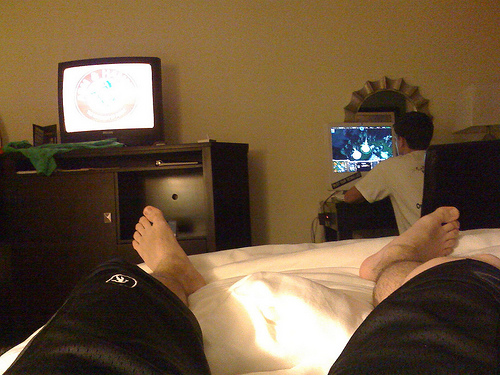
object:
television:
[54, 54, 169, 141]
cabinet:
[5, 145, 253, 336]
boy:
[346, 116, 433, 231]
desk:
[319, 200, 402, 242]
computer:
[326, 123, 397, 193]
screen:
[333, 126, 393, 171]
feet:
[130, 202, 204, 292]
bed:
[4, 227, 499, 374]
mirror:
[356, 90, 413, 113]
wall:
[0, 5, 500, 134]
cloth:
[7, 139, 121, 171]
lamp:
[448, 82, 499, 144]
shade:
[453, 83, 496, 136]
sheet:
[192, 241, 371, 374]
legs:
[6, 275, 214, 373]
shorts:
[7, 258, 500, 375]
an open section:
[118, 171, 213, 235]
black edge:
[61, 128, 167, 144]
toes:
[143, 205, 164, 223]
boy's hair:
[394, 112, 435, 149]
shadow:
[162, 64, 180, 145]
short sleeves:
[356, 149, 429, 230]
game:
[332, 126, 391, 171]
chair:
[419, 145, 499, 230]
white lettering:
[105, 272, 138, 288]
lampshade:
[455, 82, 499, 135]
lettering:
[102, 131, 114, 134]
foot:
[355, 205, 464, 282]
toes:
[435, 206, 460, 222]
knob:
[103, 211, 112, 224]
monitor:
[323, 120, 401, 190]